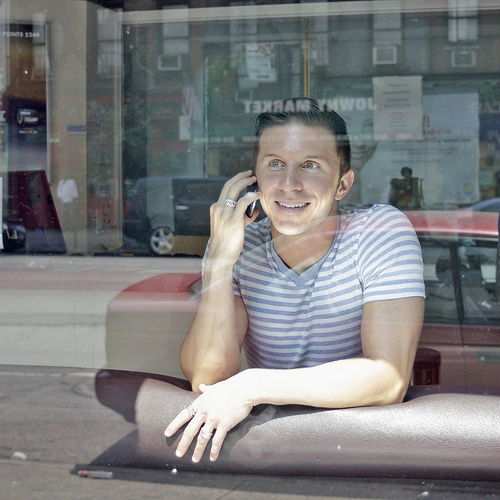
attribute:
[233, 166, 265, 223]
cell phone — black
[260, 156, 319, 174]
eyes — blue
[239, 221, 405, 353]
shirt — striped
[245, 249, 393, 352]
shirt — blue, white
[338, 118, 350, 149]
hair — short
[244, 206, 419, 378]
shirt — striped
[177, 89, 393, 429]
he — smiling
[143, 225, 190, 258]
tire — car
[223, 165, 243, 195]
finger — man's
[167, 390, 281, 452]
hand — man's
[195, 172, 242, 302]
hand — man's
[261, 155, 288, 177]
eye — man's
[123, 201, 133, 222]
light — brake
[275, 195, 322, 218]
teeth — man's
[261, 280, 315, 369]
stripes — blue, white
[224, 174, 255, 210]
finger — ring finger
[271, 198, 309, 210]
mouth — slightly open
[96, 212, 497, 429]
car — red, reflection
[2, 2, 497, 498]
window — glass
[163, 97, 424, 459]
man — smiling